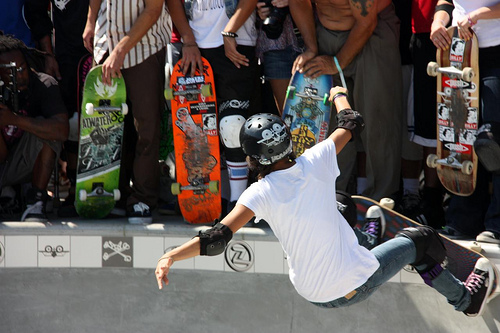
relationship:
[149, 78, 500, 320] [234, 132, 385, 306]
boy in white shirt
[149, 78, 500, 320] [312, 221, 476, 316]
skateboarder in jeans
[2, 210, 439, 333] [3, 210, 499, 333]
shadows on ground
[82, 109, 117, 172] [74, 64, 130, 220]
graphic on five skateboards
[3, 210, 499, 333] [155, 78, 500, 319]
surface for skateboarder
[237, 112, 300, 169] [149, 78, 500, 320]
helmet on skateboarder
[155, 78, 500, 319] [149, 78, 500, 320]
skateboarder observing skateboarder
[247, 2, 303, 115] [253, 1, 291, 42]
person has a camera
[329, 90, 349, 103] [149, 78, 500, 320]
wristband on skateboarder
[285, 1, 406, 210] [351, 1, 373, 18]
person has a tattoo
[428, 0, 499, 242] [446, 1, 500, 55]
person wearing a white shirt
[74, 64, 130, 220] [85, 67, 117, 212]
five skateboards with a green bottom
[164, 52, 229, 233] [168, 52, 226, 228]
skateboard has an orange bottom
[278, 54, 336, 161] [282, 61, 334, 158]
skateboard has a blue bottom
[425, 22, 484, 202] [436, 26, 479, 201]
skateboard has a tan bottom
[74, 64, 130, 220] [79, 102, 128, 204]
five skateboards has wheels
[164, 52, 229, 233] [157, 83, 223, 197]
skateboard has yellow wheels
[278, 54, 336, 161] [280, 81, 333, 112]
skateboard has green wheels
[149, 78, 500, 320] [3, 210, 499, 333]
skateboarder going up ground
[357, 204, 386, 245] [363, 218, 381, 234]
shoe has purple laces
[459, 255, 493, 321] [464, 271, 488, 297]
shoe has pink laces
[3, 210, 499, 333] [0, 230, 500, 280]
ground has a white top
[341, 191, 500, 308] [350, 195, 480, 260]
skateboard has am edge